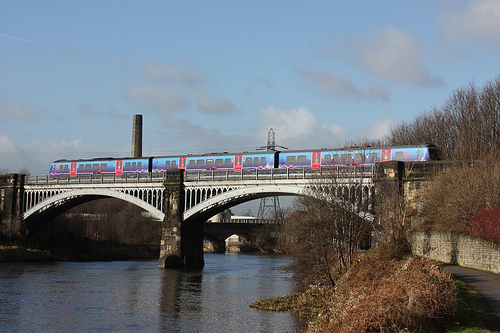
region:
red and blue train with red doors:
[42, 141, 445, 183]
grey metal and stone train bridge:
[2, 171, 423, 281]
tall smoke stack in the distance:
[127, 111, 145, 168]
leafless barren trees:
[350, 74, 499, 171]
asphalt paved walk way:
[378, 240, 498, 322]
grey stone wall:
[407, 220, 499, 279]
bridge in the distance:
[74, 203, 311, 259]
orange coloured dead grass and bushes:
[292, 245, 461, 331]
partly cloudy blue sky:
[1, 0, 498, 152]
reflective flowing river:
[0, 249, 320, 331]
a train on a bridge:
[17, 92, 497, 263]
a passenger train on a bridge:
[5, 70, 460, 251]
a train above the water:
[44, 107, 365, 305]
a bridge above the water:
[22, 120, 445, 329]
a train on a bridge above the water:
[44, 95, 397, 320]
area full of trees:
[316, 80, 474, 327]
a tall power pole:
[232, 90, 336, 274]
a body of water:
[68, 253, 123, 328]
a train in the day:
[62, 47, 418, 328]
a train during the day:
[72, 104, 297, 250]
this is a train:
[400, 142, 429, 163]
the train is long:
[223, 148, 300, 168]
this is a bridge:
[139, 171, 201, 227]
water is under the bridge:
[192, 258, 244, 311]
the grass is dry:
[360, 250, 423, 332]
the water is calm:
[159, 274, 243, 329]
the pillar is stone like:
[156, 202, 183, 267]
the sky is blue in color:
[158, 5, 233, 57]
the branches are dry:
[450, 98, 485, 183]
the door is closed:
[233, 153, 243, 168]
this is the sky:
[120, 6, 230, 40]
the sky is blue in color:
[145, 6, 214, 33]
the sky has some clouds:
[136, 70, 366, 122]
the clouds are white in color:
[274, 35, 425, 112]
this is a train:
[42, 144, 442, 176]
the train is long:
[45, 143, 447, 175]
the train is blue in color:
[261, 153, 271, 163]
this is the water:
[61, 267, 211, 294]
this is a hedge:
[330, 270, 410, 315]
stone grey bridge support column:
[163, 171, 204, 268]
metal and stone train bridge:
[24, 175, 166, 215]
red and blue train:
[51, 146, 433, 178]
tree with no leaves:
[281, 178, 379, 280]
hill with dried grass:
[301, 253, 464, 332]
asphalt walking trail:
[421, 255, 498, 299]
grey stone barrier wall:
[414, 228, 499, 268]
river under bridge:
[1, 245, 313, 332]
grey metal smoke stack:
[131, 115, 145, 157]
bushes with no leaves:
[425, 166, 499, 234]